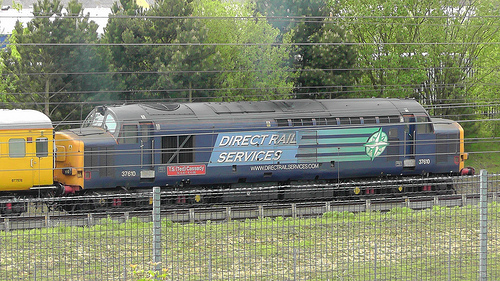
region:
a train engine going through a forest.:
[49, 59, 472, 220]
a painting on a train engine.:
[200, 105, 403, 188]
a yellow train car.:
[0, 68, 79, 208]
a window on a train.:
[149, 115, 206, 183]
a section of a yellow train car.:
[0, 62, 67, 249]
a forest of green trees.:
[0, 0, 498, 122]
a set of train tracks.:
[3, 157, 498, 229]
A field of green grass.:
[0, 193, 498, 278]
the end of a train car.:
[441, 105, 478, 182]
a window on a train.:
[84, 96, 132, 143]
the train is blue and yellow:
[83, 107, 461, 203]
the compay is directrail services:
[192, 123, 303, 167]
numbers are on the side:
[418, 157, 437, 176]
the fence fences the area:
[10, 183, 499, 272]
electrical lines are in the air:
[258, 10, 386, 130]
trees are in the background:
[151, 18, 464, 95]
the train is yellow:
[8, 113, 60, 208]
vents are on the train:
[283, 103, 405, 135]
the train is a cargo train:
[18, 97, 470, 198]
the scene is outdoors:
[3, 5, 488, 278]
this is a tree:
[174, 11, 311, 110]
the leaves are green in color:
[228, 36, 258, 71]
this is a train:
[114, 115, 484, 182]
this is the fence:
[264, 206, 373, 250]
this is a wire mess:
[300, 222, 392, 275]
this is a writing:
[208, 130, 298, 172]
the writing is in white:
[208, 130, 293, 167]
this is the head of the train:
[71, 102, 473, 154]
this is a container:
[19, 113, 54, 178]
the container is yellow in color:
[4, 158, 38, 181]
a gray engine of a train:
[53, 88, 487, 199]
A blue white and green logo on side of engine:
[207, 125, 399, 177]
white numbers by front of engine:
[416, 153, 433, 167]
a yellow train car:
[1, 85, 66, 217]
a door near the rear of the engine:
[136, 116, 168, 179]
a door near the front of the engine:
[400, 113, 429, 161]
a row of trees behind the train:
[5, 10, 499, 115]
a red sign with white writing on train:
[158, 156, 217, 181]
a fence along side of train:
[11, 165, 498, 278]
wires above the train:
[15, 12, 499, 134]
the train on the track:
[0, 96, 474, 201]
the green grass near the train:
[3, 200, 497, 277]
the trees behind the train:
[0, 0, 499, 148]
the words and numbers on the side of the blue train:
[83, 114, 460, 189]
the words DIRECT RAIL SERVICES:
[218, 133, 298, 160]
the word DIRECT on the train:
[218, 135, 267, 145]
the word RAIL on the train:
[267, 132, 294, 143]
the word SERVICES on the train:
[216, 150, 282, 160]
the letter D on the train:
[218, 134, 230, 145]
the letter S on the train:
[216, 150, 226, 162]